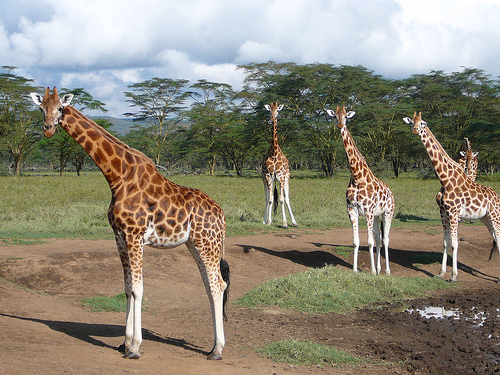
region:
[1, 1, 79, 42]
white clouds in blue sky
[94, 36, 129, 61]
white clouds in blue sky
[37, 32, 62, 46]
white clouds in blue sky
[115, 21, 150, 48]
white clouds in blue sky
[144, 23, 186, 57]
white clouds in blue sky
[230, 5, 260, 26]
white clouds in blue sky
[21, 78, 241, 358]
tan and brown giraffe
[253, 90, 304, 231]
tan and brown giraffe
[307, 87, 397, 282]
tan and brown giraffe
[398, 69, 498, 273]
tan and brown giraffe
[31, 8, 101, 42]
white clouds in blue sky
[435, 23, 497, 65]
white clouds in blue sky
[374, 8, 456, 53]
white clouds in blue sky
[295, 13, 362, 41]
white clouds in blue sky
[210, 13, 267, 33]
white clouds in blue sky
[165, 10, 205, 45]
white clouds in blue sky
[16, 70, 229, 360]
tan and brown spotted giraffe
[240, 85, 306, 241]
tan and brown spotted giraffe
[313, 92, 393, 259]
tan and brown spotted giraffe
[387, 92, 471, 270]
tan and brown spotted giraffe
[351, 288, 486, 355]
mud in front of the giraffe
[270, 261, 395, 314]
grass next to the mud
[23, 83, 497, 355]
giraffes standing in the dirt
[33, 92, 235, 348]
a giraffe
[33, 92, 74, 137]
the head of the giraffe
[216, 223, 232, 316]
the tail on the giraffe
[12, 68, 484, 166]
trees behind the giraffe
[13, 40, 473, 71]
clouds in the sky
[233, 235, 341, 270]
a shadow on the ground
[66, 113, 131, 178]
the neck of the giraffe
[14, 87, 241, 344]
tall giraffe in field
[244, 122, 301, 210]
tall giraffe in field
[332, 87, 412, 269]
tall giraffe in field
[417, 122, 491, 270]
tall giraffe in field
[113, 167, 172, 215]
brown spots on giraffe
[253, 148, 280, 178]
brown spots on giraffe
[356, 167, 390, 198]
brown spots on giraffe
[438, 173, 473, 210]
brown spots on giraffe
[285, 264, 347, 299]
green grass growing by giraffes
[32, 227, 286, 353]
dirt patches in grass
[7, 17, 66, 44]
white clouds in blue sky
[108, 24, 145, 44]
white clouds in blue sky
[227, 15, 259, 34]
white clouds in blue sky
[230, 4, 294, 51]
white clouds in blue sky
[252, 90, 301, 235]
giraffe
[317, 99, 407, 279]
giraffe